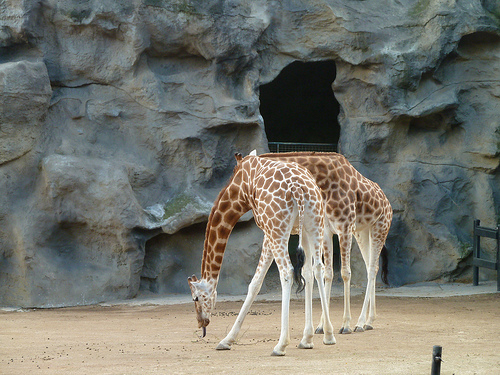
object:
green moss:
[156, 191, 196, 220]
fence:
[268, 143, 338, 153]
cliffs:
[1, 0, 497, 299]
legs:
[321, 230, 382, 325]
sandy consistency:
[23, 321, 206, 364]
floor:
[0, 293, 497, 374]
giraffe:
[183, 155, 335, 368]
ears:
[186, 276, 193, 286]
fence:
[467, 216, 499, 295]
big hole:
[256, 54, 342, 154]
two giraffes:
[181, 146, 392, 364]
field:
[42, 304, 199, 372]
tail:
[292, 193, 306, 297]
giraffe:
[229, 149, 390, 335]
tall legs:
[262, 201, 298, 345]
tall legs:
[228, 224, 277, 334]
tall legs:
[304, 194, 336, 334]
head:
[183, 275, 219, 338]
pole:
[431, 346, 444, 375]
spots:
[196, 151, 324, 277]